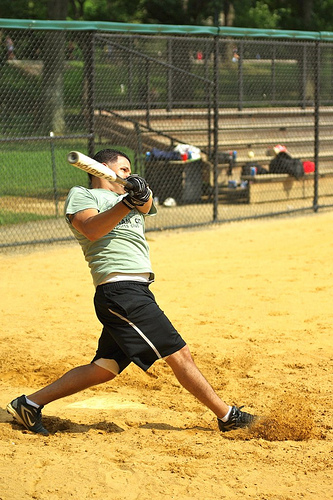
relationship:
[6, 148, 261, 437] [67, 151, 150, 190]
man swinging bat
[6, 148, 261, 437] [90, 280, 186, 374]
man wearing shorts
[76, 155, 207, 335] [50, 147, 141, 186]
man holding bat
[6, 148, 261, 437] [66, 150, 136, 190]
man swinging bat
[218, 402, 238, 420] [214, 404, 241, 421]
sock on ankle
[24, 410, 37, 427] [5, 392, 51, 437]
logo on cleats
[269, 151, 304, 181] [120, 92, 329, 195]
bag on bleachers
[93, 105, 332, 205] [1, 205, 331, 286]
bleacher by field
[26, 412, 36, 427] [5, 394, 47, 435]
logo on shoe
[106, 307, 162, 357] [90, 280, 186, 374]
stripe on shorts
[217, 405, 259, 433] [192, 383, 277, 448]
cleats on foot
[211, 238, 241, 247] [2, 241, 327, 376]
dirt on ground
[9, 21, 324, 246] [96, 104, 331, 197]
fence near bleachers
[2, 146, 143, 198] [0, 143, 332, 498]
grass on ground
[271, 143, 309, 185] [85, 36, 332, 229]
bag on bleachers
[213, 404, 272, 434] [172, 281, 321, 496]
foot in dirt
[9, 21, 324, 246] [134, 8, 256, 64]
fence has green top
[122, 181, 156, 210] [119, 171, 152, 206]
gloves for hands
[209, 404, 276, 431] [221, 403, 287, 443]
cleats kicking dirt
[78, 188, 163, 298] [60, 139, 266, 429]
shirt on man